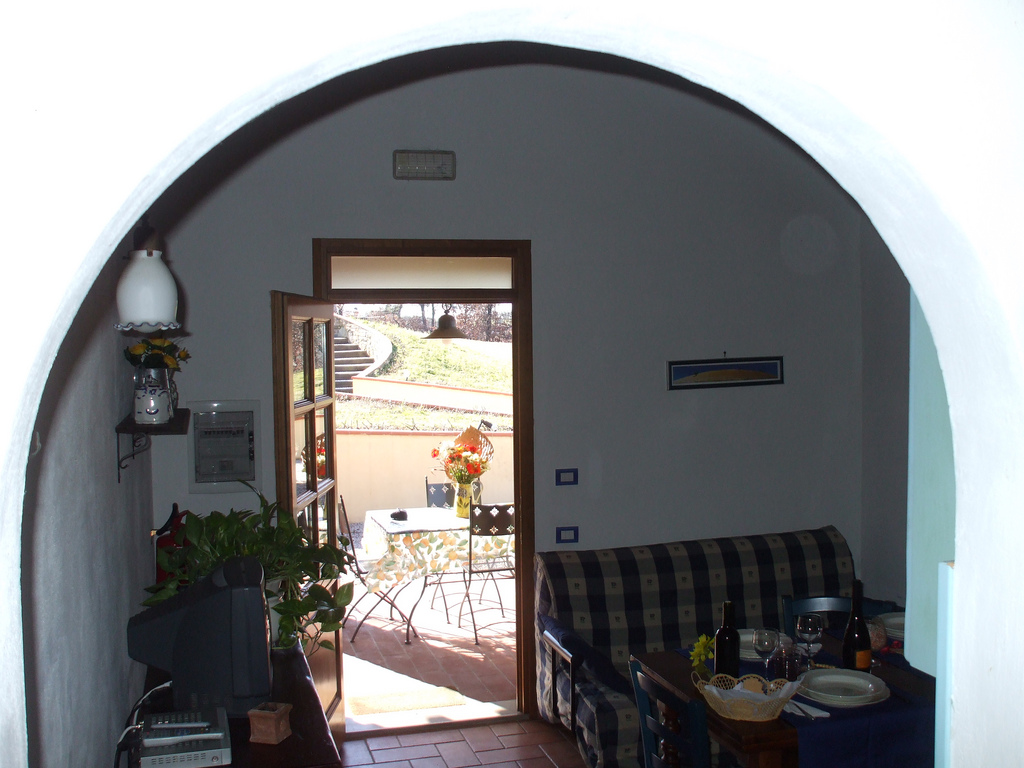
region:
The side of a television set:
[114, 548, 286, 720]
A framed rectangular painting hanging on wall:
[652, 339, 793, 397]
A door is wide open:
[256, 219, 554, 738]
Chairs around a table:
[315, 465, 524, 658]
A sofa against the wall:
[519, 514, 906, 758]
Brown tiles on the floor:
[336, 701, 593, 765]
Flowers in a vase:
[419, 430, 492, 520]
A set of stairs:
[315, 307, 382, 399]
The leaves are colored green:
[125, 482, 363, 666]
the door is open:
[295, 212, 558, 745]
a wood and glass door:
[275, 285, 359, 567]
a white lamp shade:
[114, 234, 188, 345]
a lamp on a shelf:
[101, 234, 191, 430]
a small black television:
[120, 561, 307, 718]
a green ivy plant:
[136, 488, 358, 666]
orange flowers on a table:
[433, 421, 495, 530]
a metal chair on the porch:
[332, 493, 434, 672]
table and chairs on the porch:
[349, 500, 515, 666]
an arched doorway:
[2, 9, 1015, 766]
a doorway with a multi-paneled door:
[272, 236, 536, 721]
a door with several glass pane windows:
[269, 293, 342, 718]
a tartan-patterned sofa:
[529, 525, 907, 766]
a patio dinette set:
[336, 477, 515, 652]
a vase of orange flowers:
[427, 423, 486, 516]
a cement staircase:
[327, 328, 376, 395]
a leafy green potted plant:
[143, 477, 352, 651]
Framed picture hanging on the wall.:
[661, 351, 797, 393]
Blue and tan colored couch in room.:
[540, 549, 898, 742]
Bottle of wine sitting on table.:
[710, 597, 750, 681]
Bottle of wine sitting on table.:
[833, 579, 881, 671]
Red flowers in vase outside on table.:
[446, 443, 485, 489]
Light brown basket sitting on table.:
[697, 661, 793, 723]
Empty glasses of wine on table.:
[751, 604, 834, 674]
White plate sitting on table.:
[793, 666, 891, 706]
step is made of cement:
[323, 334, 352, 347]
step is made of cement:
[324, 340, 356, 351]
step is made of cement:
[335, 352, 375, 363]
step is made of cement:
[330, 369, 353, 376]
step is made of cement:
[335, 378, 356, 388]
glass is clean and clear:
[308, 318, 331, 399]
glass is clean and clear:
[286, 318, 307, 402]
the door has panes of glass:
[266, 290, 340, 709]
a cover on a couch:
[539, 525, 872, 716]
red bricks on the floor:
[342, 721, 571, 764]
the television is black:
[119, 572, 271, 703]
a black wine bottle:
[715, 598, 747, 676]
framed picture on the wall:
[662, 351, 790, 400]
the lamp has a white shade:
[102, 200, 188, 338]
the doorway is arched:
[5, 34, 1021, 766]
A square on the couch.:
[603, 574, 630, 597]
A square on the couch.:
[623, 576, 643, 589]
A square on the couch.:
[638, 570, 655, 586]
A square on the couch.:
[641, 601, 664, 624]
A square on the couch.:
[612, 611, 631, 625]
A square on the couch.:
[572, 605, 589, 629]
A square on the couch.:
[710, 563, 731, 586]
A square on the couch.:
[739, 566, 758, 586]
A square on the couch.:
[739, 599, 765, 615]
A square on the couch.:
[777, 560, 796, 581]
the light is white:
[40, 244, 206, 337]